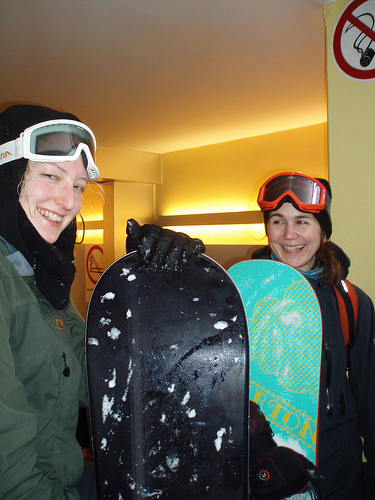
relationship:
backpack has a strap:
[306, 258, 370, 339] [330, 272, 360, 350]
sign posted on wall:
[335, 4, 372, 80] [323, 4, 375, 276]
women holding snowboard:
[3, 98, 374, 499] [80, 244, 252, 499]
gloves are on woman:
[122, 218, 203, 273] [218, 160, 374, 498]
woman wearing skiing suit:
[218, 160, 374, 498] [300, 269, 374, 495]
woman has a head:
[218, 160, 374, 498] [254, 173, 328, 264]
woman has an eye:
[218, 160, 374, 498] [272, 215, 284, 228]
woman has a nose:
[218, 160, 374, 498] [282, 222, 301, 243]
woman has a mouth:
[218, 160, 374, 498] [275, 239, 311, 256]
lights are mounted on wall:
[154, 112, 340, 241] [323, 4, 375, 276]